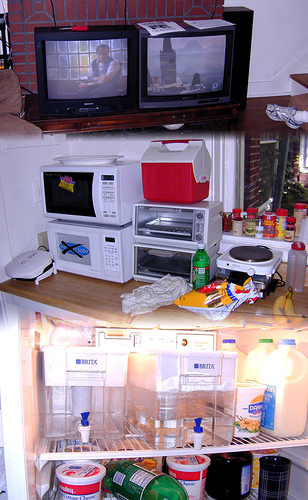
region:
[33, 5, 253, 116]
two black tvs on a shelf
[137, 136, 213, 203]
red and white cooler on top of the toaster oven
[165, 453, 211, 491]
red and white round container in the refrigerator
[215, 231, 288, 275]
hot plate sitting on the counter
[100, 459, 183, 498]
green bottle lying down in the refrigerator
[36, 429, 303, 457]
white shelf in the refrigerator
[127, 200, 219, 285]
tow toaster ovens on top of each other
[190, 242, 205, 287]
green bottle sitting on the counter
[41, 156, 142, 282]
two microwave ovens on top of each other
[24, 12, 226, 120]
Two television on the shelf.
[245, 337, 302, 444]
Milk in the refrigerator.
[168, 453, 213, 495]
A container of cottage cheese in the fidge.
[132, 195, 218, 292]
Two toaster over stacked on top of each other.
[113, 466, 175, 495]
A bottle of soda on the shelf.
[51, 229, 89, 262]
An x marked on the microwave.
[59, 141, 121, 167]
A white plate on the microwave.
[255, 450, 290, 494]
A black cup in the refrigerator.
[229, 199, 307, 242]
Seasoning on the window pane.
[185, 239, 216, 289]
A bottle of soda on the counter top.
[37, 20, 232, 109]
two televisions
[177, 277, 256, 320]
an open bag of chips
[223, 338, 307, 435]
three half gallons of milk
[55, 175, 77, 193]
a sticker on the front of the microwave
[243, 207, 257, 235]
the spice bottle has a red lid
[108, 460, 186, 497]
the soda bottle is laying over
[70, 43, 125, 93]
a man on the Tv picture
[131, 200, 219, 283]
two stacked toaster ovens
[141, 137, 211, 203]
a large red ice chest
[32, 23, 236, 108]
Two televisions on a table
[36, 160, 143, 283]
Two microwaves stacked together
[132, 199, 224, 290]
Two toaster ovens stacked together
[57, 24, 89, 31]
Screwdriver with a red handle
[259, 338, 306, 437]
A full half gallon of milk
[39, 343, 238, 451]
Two Brita water purifiers in a refrigerator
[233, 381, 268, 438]
A container of Dannon yogurt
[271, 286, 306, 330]
Two bananas on a counter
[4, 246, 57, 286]
George Foreman grill on a counter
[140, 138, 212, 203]
Red and white cooler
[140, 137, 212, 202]
a red and white cooler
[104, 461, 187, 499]
a green two liter soda bottle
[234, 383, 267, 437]
a tub of yoghurt on a shelf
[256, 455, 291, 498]
a black mug in a refrigerator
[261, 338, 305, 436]
a half gallon of milk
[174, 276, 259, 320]
a bag of chips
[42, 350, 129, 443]
a Brita water filter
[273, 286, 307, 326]
two yellow bananas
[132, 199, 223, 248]
a white toaster oven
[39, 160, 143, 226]
a white microwave oven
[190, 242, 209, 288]
green plastic bottle with a white lid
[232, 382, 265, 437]
white Dannon yogurt container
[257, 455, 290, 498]
black coffee mug with white design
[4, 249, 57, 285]
white George Foreman grill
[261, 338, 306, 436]
milk with a light blue lid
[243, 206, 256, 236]
bottle of oregano leaves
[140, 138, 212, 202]
red cooler with a white lid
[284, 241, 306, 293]
clear plastic bottle with a red lid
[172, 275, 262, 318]
yellow bag of chips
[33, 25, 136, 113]
small CRT color television monitor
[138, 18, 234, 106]
small CRT color television monitor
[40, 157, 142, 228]
small white microwave oven